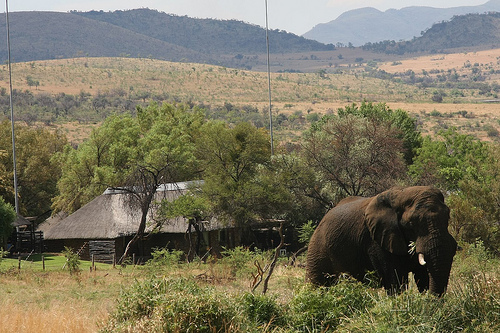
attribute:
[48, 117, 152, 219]
leaves — green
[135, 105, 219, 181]
leaves — green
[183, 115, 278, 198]
leaves — green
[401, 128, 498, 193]
leaves — green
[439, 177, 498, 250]
leaves — green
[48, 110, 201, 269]
tree — brown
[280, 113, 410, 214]
tree — brown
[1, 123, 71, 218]
tree — brown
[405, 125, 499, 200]
tree — brown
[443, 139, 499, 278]
tree — brown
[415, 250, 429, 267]
tusk — white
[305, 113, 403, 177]
leaves — green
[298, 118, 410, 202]
tree — brown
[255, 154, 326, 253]
tree — brown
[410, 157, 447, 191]
tree — brown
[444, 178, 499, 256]
tree — brown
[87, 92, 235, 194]
leaves — green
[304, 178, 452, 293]
elephant — brown , large 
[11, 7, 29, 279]
pole — metal, large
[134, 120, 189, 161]
leaves — green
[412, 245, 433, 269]
tusk — white 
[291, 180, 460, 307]
elephant — brown, large, gray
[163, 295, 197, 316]
leaves — green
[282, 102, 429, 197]
trees — brown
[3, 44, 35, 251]
pole — metal , large 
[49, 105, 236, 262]
trees — large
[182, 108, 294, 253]
trees — large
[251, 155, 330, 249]
trees — large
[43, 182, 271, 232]
roof — gray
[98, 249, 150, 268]
fence — post , wood 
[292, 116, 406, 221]
tree — brown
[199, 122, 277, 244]
tree — brown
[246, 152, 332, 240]
tree — brown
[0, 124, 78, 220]
tree — brown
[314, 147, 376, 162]
leaves — green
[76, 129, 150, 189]
leaves — green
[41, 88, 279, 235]
trees — brown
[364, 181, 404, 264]
ear — big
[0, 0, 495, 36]
sky — white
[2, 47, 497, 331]
ground — brown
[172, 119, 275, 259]
tree — brown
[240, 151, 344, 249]
tree — brown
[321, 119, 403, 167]
leaves — green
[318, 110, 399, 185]
leaves — green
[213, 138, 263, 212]
leaves — green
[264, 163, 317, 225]
leaves — green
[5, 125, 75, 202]
leaves — green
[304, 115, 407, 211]
tree — brown